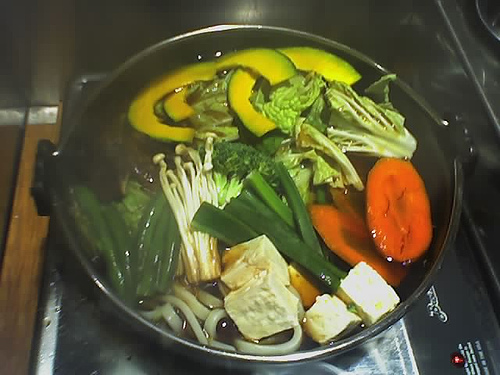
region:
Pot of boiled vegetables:
[32, 21, 472, 362]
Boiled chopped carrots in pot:
[310, 155, 431, 280]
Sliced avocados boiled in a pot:
[126, 45, 356, 131]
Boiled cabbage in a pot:
[261, 72, 321, 124]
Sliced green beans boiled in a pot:
[75, 185, 175, 300]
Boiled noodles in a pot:
[144, 279, 304, 352]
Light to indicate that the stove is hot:
[448, 350, 467, 367]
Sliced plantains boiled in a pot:
[294, 262, 401, 342]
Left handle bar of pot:
[25, 139, 57, 216]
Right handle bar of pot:
[449, 109, 494, 186]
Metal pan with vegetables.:
[36, 25, 458, 362]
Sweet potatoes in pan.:
[312, 156, 442, 279]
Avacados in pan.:
[125, 49, 354, 148]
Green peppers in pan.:
[190, 167, 345, 287]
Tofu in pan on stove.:
[219, 238, 402, 341]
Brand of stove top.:
[417, 286, 486, 373]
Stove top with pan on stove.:
[5, 6, 493, 367]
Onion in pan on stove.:
[136, 283, 326, 358]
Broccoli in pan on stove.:
[262, 76, 422, 188]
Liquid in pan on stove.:
[87, 108, 309, 349]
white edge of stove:
[28, 316, 70, 351]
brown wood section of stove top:
[8, 214, 36, 282]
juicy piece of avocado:
[245, 43, 295, 85]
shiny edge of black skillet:
[167, 18, 256, 42]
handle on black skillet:
[13, 134, 91, 206]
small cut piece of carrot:
[356, 154, 438, 285]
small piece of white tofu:
[325, 249, 419, 330]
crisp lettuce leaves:
[251, 88, 386, 205]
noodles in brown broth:
[159, 286, 301, 373]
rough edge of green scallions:
[187, 147, 358, 263]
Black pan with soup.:
[7, 0, 481, 367]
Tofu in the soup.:
[221, 216, 405, 343]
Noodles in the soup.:
[110, 267, 315, 352]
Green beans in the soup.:
[59, 156, 201, 317]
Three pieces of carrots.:
[272, 112, 454, 302]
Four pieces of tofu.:
[185, 228, 423, 357]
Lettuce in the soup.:
[230, 53, 440, 191]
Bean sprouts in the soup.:
[143, 112, 249, 297]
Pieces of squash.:
[96, 37, 383, 149]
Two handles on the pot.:
[28, 111, 497, 226]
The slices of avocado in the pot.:
[133, 60, 365, 137]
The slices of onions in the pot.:
[161, 265, 302, 360]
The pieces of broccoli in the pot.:
[205, 138, 290, 199]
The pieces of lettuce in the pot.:
[266, 68, 413, 190]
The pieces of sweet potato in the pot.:
[305, 158, 434, 293]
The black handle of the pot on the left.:
[25, 137, 56, 211]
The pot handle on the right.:
[438, 103, 478, 173]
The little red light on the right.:
[441, 335, 471, 374]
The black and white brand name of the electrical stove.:
[416, 278, 449, 323]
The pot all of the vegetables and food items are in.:
[46, 32, 473, 367]